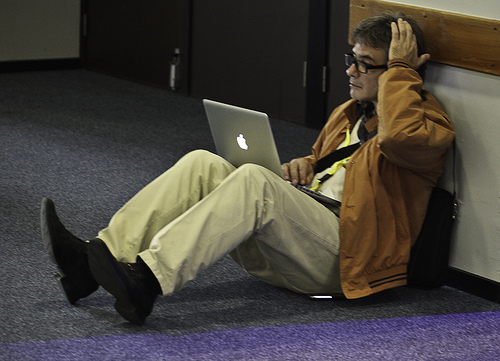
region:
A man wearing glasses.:
[332, 10, 445, 107]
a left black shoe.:
[84, 225, 164, 322]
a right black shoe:
[29, 183, 112, 318]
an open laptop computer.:
[193, 82, 285, 177]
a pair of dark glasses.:
[340, 38, 387, 88]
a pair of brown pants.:
[81, 151, 362, 323]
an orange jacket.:
[289, 60, 464, 314]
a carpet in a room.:
[1, 60, 497, 359]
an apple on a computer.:
[229, 130, 259, 153]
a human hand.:
[378, 12, 447, 79]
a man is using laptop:
[206, 12, 415, 220]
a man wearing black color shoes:
[31, 194, 157, 317]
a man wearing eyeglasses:
[345, 48, 382, 77]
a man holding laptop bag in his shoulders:
[306, 82, 464, 286]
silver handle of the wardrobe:
[165, 49, 182, 97]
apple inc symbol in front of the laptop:
[231, 123, 254, 156]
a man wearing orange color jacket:
[316, 88, 419, 286]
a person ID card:
[298, 180, 344, 208]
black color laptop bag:
[421, 182, 452, 280]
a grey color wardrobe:
[201, 27, 303, 104]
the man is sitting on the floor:
[35, 8, 495, 337]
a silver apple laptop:
[193, 83, 342, 215]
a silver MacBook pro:
[198, 83, 360, 210]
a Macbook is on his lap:
[195, 90, 350, 217]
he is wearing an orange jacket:
[288, 2, 478, 312]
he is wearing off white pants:
[96, 147, 377, 331]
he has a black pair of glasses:
[336, 42, 396, 79]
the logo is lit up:
[230, 123, 260, 153]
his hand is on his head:
[380, 13, 440, 68]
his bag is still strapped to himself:
[395, 95, 472, 307]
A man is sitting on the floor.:
[38, 12, 453, 324]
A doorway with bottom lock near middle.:
[79, 1, 327, 126]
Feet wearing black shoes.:
[38, 197, 154, 327]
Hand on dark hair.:
[386, 17, 429, 75]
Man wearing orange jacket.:
[306, 57, 454, 300]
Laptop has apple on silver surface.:
[203, 99, 340, 205]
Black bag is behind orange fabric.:
[403, 127, 470, 286]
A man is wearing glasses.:
[345, 47, 390, 72]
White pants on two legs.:
[88, 146, 341, 296]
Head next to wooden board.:
[348, 1, 497, 76]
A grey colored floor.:
[4, 64, 496, 357]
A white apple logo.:
[233, 132, 252, 152]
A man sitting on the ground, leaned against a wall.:
[35, 10, 473, 326]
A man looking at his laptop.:
[36, 12, 451, 329]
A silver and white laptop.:
[201, 94, 347, 206]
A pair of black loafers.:
[39, 194, 166, 322]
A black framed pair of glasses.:
[340, 51, 385, 74]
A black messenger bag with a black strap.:
[309, 147, 451, 291]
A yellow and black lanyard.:
[301, 122, 356, 194]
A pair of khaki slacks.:
[97, 146, 347, 301]